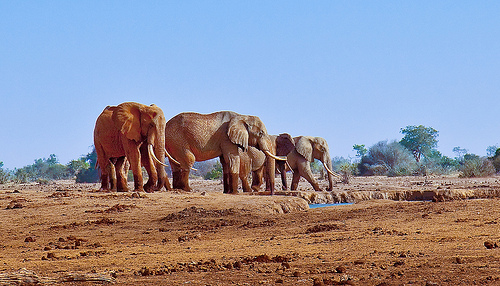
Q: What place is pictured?
A: It is a desert.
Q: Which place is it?
A: It is a desert.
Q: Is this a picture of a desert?
A: Yes, it is showing a desert.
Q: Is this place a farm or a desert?
A: It is a desert.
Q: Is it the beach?
A: No, it is the desert.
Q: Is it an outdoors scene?
A: Yes, it is outdoors.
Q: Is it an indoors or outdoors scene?
A: It is outdoors.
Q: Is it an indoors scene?
A: No, it is outdoors.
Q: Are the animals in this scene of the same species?
A: Yes, all the animals are elephants.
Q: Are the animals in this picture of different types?
A: No, all the animals are elephants.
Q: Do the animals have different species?
A: No, all the animals are elephants.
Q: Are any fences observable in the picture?
A: No, there are no fences.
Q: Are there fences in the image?
A: No, there are no fences.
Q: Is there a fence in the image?
A: No, there are no fences.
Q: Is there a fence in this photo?
A: No, there are no fences.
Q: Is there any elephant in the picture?
A: Yes, there is an elephant.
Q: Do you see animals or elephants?
A: Yes, there is an elephant.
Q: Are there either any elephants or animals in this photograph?
A: Yes, there is an elephant.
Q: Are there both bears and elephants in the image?
A: No, there is an elephant but no bears.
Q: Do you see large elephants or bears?
A: Yes, there is a large elephant.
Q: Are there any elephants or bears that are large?
A: Yes, the elephant is large.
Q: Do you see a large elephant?
A: Yes, there is a large elephant.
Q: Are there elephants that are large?
A: Yes, there is an elephant that is large.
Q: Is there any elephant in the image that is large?
A: Yes, there is an elephant that is large.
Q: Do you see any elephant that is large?
A: Yes, there is an elephant that is large.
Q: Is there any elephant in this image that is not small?
A: Yes, there is a large elephant.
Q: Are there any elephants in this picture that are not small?
A: Yes, there is a large elephant.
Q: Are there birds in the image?
A: No, there are no birds.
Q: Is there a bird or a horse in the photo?
A: No, there are no birds or horses.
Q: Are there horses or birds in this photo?
A: No, there are no birds or horses.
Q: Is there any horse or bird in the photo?
A: No, there are no birds or horses.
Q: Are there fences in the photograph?
A: No, there are no fences.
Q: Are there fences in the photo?
A: No, there are no fences.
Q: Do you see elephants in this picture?
A: Yes, there is an elephant.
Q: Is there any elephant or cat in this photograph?
A: Yes, there is an elephant.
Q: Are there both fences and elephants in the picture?
A: No, there is an elephant but no fences.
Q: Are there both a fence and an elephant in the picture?
A: No, there is an elephant but no fences.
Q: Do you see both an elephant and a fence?
A: No, there is an elephant but no fences.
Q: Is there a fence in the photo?
A: No, there are no fences.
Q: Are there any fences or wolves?
A: No, there are no fences or wolves.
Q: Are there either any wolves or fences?
A: No, there are no fences or wolves.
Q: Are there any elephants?
A: Yes, there is an elephant.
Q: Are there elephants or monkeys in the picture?
A: Yes, there is an elephant.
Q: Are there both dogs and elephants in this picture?
A: No, there is an elephant but no dogs.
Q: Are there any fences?
A: No, there are no fences.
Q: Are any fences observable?
A: No, there are no fences.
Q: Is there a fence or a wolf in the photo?
A: No, there are no fences or wolves.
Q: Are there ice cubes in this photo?
A: No, there are no ice cubes.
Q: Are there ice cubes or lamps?
A: No, there are no ice cubes or lamps.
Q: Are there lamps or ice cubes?
A: No, there are no ice cubes or lamps.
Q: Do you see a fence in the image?
A: No, there are no fences.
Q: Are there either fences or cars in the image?
A: No, there are no fences or cars.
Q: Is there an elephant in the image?
A: Yes, there is an elephant.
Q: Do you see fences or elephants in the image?
A: Yes, there is an elephant.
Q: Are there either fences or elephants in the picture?
A: Yes, there is an elephant.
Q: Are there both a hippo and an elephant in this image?
A: No, there is an elephant but no hippos.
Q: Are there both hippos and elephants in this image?
A: No, there is an elephant but no hippos.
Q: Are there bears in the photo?
A: No, there are no bears.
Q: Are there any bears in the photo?
A: No, there are no bears.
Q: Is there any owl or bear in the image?
A: No, there are no bears or owls.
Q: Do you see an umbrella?
A: No, there are no umbrellas.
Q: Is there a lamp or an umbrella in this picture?
A: No, there are no umbrellas or lamps.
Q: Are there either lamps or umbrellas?
A: No, there are no umbrellas or lamps.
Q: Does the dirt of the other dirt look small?
A: Yes, the dirt is small.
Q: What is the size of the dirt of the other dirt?
A: The dirt is small.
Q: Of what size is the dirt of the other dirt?
A: The dirt is small.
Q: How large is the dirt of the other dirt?
A: The dirt is small.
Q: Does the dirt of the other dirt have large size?
A: No, the dirt is small.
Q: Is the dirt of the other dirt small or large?
A: The dirt is small.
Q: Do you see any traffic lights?
A: No, there are no traffic lights.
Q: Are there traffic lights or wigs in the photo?
A: No, there are no traffic lights or wigs.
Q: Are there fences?
A: No, there are no fences.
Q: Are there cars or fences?
A: No, there are no fences or cars.